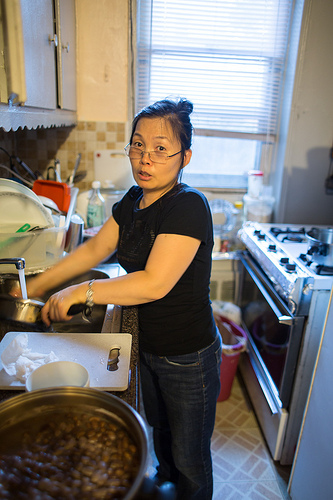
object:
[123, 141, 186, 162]
glasses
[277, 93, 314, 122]
wall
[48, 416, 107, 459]
beans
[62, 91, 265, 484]
woman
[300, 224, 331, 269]
pot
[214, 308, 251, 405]
bind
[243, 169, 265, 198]
bottle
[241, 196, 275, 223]
bottle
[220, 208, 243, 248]
bottle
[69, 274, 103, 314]
bracelet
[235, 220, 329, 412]
oven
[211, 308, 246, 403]
garbage bin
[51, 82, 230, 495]
woman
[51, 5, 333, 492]
kitchen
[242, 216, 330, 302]
stove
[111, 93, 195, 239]
green grass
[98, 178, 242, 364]
tshirt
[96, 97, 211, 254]
woman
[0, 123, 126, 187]
tile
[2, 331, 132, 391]
cutting board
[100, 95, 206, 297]
woman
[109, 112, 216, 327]
woman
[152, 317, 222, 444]
jeans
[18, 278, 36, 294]
water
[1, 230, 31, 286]
faucet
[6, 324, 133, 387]
board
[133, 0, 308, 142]
blinds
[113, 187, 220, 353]
shirt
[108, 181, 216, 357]
shirt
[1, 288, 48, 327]
pan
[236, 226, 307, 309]
aluminum foil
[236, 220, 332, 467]
stove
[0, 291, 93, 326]
pot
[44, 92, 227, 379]
woman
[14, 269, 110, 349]
pot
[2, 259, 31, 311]
faucet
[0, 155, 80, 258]
cooking utensils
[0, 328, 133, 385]
cooking utensils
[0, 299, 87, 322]
cooking utensils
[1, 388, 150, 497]
cooking utensils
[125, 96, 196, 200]
woman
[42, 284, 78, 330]
hand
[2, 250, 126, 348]
sink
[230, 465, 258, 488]
tile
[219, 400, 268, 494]
floor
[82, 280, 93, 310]
bracelet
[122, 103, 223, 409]
woman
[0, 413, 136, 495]
beans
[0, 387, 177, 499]
pot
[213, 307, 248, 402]
bin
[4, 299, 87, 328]
pan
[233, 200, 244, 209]
lid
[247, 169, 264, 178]
lid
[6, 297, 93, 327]
pan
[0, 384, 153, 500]
pot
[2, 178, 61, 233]
dishes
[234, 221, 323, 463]
stove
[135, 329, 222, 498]
jeans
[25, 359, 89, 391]
container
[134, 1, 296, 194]
window